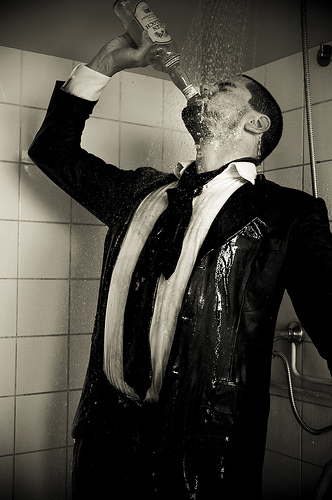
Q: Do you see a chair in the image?
A: No, there are no chairs.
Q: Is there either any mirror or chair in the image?
A: No, there are no chairs or mirrors.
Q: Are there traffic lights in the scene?
A: No, there are no traffic lights.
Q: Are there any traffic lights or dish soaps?
A: No, there are no traffic lights or dish soaps.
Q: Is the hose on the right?
A: Yes, the hose is on the right of the image.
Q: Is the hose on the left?
A: No, the hose is on the right of the image.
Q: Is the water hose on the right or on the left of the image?
A: The water hose is on the right of the image.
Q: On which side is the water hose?
A: The water hose is on the right of the image.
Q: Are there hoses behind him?
A: Yes, there is a hose behind the man.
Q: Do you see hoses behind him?
A: Yes, there is a hose behind the man.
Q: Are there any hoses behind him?
A: Yes, there is a hose behind the man.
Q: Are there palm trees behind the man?
A: No, there is a hose behind the man.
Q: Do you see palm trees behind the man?
A: No, there is a hose behind the man.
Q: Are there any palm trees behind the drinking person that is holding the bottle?
A: No, there is a hose behind the man.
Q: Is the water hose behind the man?
A: Yes, the water hose is behind the man.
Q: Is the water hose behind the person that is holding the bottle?
A: Yes, the water hose is behind the man.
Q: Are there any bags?
A: No, there are no bags.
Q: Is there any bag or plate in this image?
A: No, there are no bags or plates.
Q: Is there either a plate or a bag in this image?
A: No, there are no bags or plates.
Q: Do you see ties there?
A: Yes, there is a tie.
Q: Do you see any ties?
A: Yes, there is a tie.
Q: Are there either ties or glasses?
A: Yes, there is a tie.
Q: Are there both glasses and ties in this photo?
A: No, there is a tie but no glasses.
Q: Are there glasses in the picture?
A: No, there are no glasses.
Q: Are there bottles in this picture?
A: Yes, there is a bottle.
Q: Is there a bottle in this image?
A: Yes, there is a bottle.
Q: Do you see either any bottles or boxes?
A: Yes, there is a bottle.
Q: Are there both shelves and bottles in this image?
A: No, there is a bottle but no shelves.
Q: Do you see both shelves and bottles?
A: No, there is a bottle but no shelves.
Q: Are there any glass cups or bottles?
A: Yes, there is a glass bottle.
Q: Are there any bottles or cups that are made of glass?
A: Yes, the bottle is made of glass.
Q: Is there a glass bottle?
A: Yes, there is a bottle that is made of glass.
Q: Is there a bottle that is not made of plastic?
A: Yes, there is a bottle that is made of glass.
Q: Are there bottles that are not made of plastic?
A: Yes, there is a bottle that is made of glass.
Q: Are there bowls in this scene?
A: No, there are no bowls.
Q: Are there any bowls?
A: No, there are no bowls.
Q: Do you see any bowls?
A: No, there are no bowls.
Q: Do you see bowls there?
A: No, there are no bowls.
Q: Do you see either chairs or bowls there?
A: No, there are no bowls or chairs.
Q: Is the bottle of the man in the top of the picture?
A: Yes, the bottle is in the top of the image.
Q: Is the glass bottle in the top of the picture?
A: Yes, the bottle is in the top of the image.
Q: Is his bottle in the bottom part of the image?
A: No, the bottle is in the top of the image.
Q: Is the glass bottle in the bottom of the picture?
A: No, the bottle is in the top of the image.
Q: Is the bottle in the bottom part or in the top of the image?
A: The bottle is in the top of the image.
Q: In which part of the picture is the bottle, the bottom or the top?
A: The bottle is in the top of the image.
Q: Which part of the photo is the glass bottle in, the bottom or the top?
A: The bottle is in the top of the image.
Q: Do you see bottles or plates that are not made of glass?
A: No, there is a bottle but it is made of glass.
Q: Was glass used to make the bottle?
A: Yes, the bottle is made of glass.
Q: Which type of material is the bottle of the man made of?
A: The bottle is made of glass.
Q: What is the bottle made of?
A: The bottle is made of glass.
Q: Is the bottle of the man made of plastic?
A: No, the bottle is made of glass.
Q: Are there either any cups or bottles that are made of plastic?
A: No, there is a bottle but it is made of glass.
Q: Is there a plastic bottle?
A: No, there is a bottle but it is made of glass.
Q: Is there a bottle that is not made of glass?
A: No, there is a bottle but it is made of glass.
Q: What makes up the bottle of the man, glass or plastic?
A: The bottle is made of glass.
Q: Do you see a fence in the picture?
A: No, there are no fences.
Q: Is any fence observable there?
A: No, there are no fences.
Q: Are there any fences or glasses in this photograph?
A: No, there are no fences or glasses.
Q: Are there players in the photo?
A: No, there are no players.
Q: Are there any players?
A: No, there are no players.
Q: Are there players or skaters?
A: No, there are no players or skaters.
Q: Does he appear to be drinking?
A: Yes, the man is drinking.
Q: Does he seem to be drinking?
A: Yes, the man is drinking.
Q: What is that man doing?
A: The man is drinking.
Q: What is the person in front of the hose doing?
A: The man is drinking.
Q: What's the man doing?
A: The man is drinking.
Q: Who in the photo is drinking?
A: The man is drinking.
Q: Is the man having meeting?
A: No, the man is drinking.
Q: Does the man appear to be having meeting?
A: No, the man is drinking.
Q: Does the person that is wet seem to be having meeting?
A: No, the man is drinking.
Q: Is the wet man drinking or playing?
A: The man is drinking.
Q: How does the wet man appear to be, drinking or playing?
A: The man is drinking.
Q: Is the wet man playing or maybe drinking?
A: The man is drinking.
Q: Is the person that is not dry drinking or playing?
A: The man is drinking.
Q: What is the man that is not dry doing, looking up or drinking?
A: The man is drinking.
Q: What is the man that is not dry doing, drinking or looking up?
A: The man is drinking.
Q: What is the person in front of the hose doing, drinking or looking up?
A: The man is drinking.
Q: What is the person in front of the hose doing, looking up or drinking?
A: The man is drinking.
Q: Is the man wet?
A: Yes, the man is wet.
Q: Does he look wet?
A: Yes, the man is wet.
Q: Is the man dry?
A: No, the man is wet.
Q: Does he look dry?
A: No, the man is wet.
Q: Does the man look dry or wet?
A: The man is wet.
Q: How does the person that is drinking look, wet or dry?
A: The man is wet.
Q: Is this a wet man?
A: Yes, this is a wet man.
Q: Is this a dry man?
A: No, this is a wet man.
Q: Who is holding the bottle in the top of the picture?
A: The man is holding the bottle.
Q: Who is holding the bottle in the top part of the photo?
A: The man is holding the bottle.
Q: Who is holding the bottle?
A: The man is holding the bottle.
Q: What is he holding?
A: The man is holding the bottle.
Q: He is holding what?
A: The man is holding the bottle.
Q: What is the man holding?
A: The man is holding the bottle.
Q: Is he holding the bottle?
A: Yes, the man is holding the bottle.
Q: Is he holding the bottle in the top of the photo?
A: Yes, the man is holding the bottle.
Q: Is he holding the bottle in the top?
A: Yes, the man is holding the bottle.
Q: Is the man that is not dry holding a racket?
A: No, the man is holding the bottle.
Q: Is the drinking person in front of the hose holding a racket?
A: No, the man is holding the bottle.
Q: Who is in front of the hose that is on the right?
A: The man is in front of the water hose.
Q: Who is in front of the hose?
A: The man is in front of the water hose.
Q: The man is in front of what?
A: The man is in front of the hose.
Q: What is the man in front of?
A: The man is in front of the hose.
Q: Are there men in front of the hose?
A: Yes, there is a man in front of the hose.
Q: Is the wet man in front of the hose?
A: Yes, the man is in front of the hose.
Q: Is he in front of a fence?
A: No, the man is in front of the hose.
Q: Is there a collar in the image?
A: Yes, there is a collar.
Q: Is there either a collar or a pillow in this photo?
A: Yes, there is a collar.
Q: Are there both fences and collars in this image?
A: No, there is a collar but no fences.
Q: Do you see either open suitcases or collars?
A: Yes, there is an open collar.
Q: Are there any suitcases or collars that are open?
A: Yes, the collar is open.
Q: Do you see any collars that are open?
A: Yes, there is an open collar.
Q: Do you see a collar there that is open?
A: Yes, there is a collar that is open.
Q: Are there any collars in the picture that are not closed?
A: Yes, there is a open collar.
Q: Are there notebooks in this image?
A: No, there are no notebooks.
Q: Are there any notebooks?
A: No, there are no notebooks.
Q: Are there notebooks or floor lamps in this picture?
A: No, there are no notebooks or floor lamps.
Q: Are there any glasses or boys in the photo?
A: No, there are no glasses or boys.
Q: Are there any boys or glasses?
A: No, there are no glasses or boys.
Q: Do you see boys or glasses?
A: No, there are no glasses or boys.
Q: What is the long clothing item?
A: The clothing item is a shirt.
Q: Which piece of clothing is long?
A: The clothing item is a shirt.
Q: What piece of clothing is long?
A: The clothing item is a shirt.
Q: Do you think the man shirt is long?
A: Yes, the shirt is long.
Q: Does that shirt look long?
A: Yes, the shirt is long.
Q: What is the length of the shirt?
A: The shirt is long.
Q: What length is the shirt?
A: The shirt is long.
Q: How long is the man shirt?
A: The shirt is long.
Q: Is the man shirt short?
A: No, the shirt is long.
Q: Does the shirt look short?
A: No, the shirt is long.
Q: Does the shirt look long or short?
A: The shirt is long.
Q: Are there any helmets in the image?
A: No, there are no helmets.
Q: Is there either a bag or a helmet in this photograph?
A: No, there are no helmets or bags.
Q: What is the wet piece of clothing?
A: The clothing item is a jacket.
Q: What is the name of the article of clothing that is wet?
A: The clothing item is a jacket.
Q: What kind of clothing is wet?
A: The clothing is a jacket.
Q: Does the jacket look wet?
A: Yes, the jacket is wet.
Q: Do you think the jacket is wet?
A: Yes, the jacket is wet.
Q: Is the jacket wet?
A: Yes, the jacket is wet.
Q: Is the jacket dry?
A: No, the jacket is wet.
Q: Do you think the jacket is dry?
A: No, the jacket is wet.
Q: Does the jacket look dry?
A: No, the jacket is wet.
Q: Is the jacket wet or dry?
A: The jacket is wet.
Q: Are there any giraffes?
A: No, there are no giraffes.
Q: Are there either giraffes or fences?
A: No, there are no giraffes or fences.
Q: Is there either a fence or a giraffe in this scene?
A: No, there are no giraffes or fences.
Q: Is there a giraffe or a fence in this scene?
A: No, there are no giraffes or fences.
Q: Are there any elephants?
A: No, there are no elephants.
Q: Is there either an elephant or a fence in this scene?
A: No, there are no elephants or fences.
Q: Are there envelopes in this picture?
A: No, there are no envelopes.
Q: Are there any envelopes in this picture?
A: No, there are no envelopes.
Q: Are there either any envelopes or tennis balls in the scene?
A: No, there are no envelopes or tennis balls.